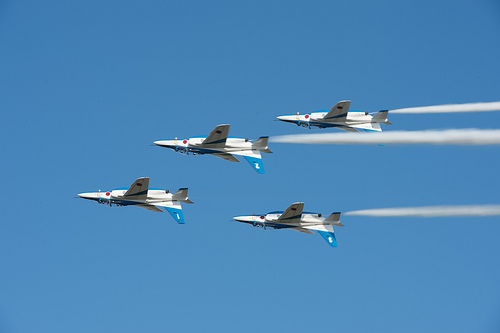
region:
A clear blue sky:
[0, 0, 499, 95]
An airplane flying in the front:
[73, 173, 199, 224]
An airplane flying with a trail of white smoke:
[233, 198, 498, 243]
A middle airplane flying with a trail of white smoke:
[146, 127, 499, 181]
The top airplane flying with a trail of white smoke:
[273, 93, 499, 131]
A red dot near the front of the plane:
[103, 188, 116, 200]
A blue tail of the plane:
[317, 225, 343, 252]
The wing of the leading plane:
[121, 170, 168, 207]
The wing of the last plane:
[321, 89, 352, 129]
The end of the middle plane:
[238, 126, 284, 173]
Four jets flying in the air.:
[70, 95, 390, 271]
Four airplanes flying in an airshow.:
[60, 88, 425, 286]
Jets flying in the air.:
[62, 87, 414, 258]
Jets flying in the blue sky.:
[26, 74, 436, 303]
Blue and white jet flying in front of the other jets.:
[76, 175, 194, 226]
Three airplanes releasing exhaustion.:
[152, 95, 498, 245]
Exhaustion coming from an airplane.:
[267, 129, 498, 145]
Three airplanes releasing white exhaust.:
[155, 89, 499, 248]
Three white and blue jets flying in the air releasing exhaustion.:
[154, 97, 497, 249]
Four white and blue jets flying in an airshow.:
[66, 89, 396, 251]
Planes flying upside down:
[71, 73, 382, 249]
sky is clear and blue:
[0, 0, 497, 330]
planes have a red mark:
[70, 85, 317, 231]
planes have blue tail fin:
[75, 75, 386, 257]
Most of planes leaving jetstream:
[150, 76, 495, 256]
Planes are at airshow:
[75, 66, 391, 251]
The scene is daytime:
[0, 0, 496, 330]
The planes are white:
[74, 82, 388, 247]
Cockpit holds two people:
[77, 183, 139, 220]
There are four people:
[68, 97, 423, 247]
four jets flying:
[18, 15, 495, 290]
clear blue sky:
[3, 11, 184, 133]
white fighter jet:
[261, 89, 498, 139]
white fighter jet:
[131, 100, 284, 175]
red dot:
[170, 124, 195, 163]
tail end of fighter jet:
[315, 200, 371, 260]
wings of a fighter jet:
[192, 112, 255, 190]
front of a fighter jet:
[265, 91, 316, 136]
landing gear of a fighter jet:
[236, 210, 307, 256]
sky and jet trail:
[406, 90, 499, 159]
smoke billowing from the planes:
[416, 99, 495, 161]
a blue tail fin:
[162, 207, 191, 226]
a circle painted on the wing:
[289, 201, 297, 213]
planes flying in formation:
[71, 70, 379, 307]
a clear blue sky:
[50, 48, 195, 123]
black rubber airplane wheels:
[181, 147, 201, 159]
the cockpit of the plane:
[171, 133, 184, 140]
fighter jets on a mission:
[67, 79, 397, 330]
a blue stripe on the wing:
[286, 212, 303, 222]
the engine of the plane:
[164, 188, 175, 196]